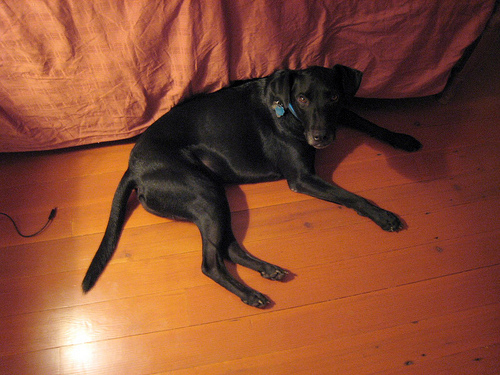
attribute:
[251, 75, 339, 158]
dog — black, looking, laying, dark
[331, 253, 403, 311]
floor — wood, wooden, brown, hard, orange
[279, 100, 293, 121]
collar — blue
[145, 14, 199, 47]
bed — made, hanging, wrinkled